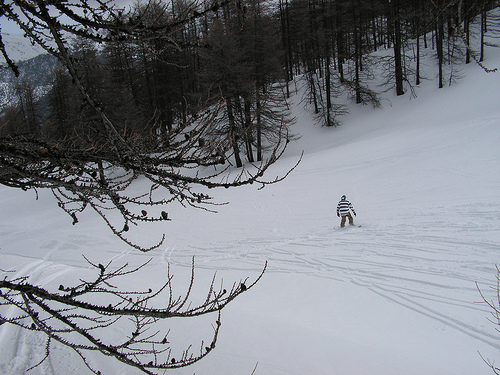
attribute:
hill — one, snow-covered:
[13, 0, 492, 141]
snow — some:
[31, 36, 495, 347]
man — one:
[333, 191, 360, 231]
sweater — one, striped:
[336, 199, 357, 215]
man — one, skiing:
[327, 186, 370, 234]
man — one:
[336, 195, 357, 230]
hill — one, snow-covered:
[160, 6, 497, 367]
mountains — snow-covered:
[9, 26, 181, 150]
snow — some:
[15, 22, 177, 148]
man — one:
[329, 190, 364, 235]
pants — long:
[339, 213, 357, 228]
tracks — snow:
[125, 202, 498, 352]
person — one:
[334, 191, 362, 231]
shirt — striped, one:
[336, 200, 356, 215]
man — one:
[295, 184, 393, 248]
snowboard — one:
[318, 215, 428, 257]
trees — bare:
[101, 7, 495, 174]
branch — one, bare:
[1, 246, 276, 374]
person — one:
[319, 188, 383, 238]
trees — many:
[5, 2, 499, 176]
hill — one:
[4, 10, 495, 182]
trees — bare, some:
[310, 52, 380, 106]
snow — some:
[366, 129, 483, 186]